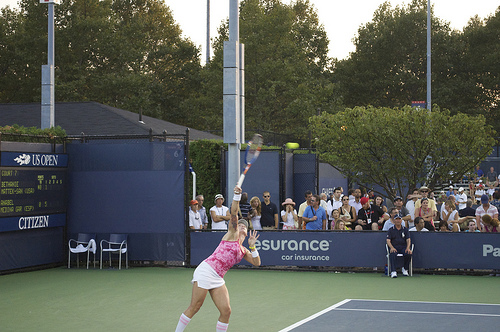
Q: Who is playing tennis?
A: A lady.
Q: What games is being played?
A: Tennis.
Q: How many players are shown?
A: 1.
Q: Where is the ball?
A: In the air.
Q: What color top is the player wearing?
A: Pink.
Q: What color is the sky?
A: White.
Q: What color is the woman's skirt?
A: White.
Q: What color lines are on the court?
A: White.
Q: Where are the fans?
A: Behind the wall.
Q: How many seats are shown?
A: 3.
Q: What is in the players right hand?
A: Racket.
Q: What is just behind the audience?
A: A tree.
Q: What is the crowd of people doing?
A: Watching a tennis match.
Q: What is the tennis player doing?
A: Serving a ball.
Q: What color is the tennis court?
A: Blue and green with white lines.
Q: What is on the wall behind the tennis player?
A: Electronic scoreboard.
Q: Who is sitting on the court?
A: An official.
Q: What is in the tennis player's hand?
A: A tennis racket.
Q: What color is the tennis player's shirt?
A: Pink.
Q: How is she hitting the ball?
A: With the racket.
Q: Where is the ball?
A: In the air.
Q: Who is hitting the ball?
A: The player.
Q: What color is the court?
A: Blue.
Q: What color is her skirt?
A: White.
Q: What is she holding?
A: Racket.